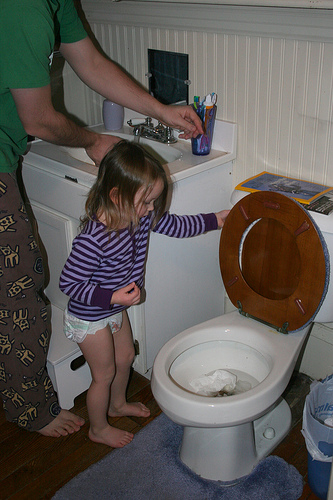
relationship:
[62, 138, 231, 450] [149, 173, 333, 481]
child flushing toilet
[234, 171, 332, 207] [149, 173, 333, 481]
magazine on top of toilet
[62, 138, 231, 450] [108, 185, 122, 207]
child has ear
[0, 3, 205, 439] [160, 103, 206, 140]
man has hand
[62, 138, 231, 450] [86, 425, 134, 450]
child has foot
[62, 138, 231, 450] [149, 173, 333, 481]
child next to toilet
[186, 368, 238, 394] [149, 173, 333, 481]
toilet paper inside of toilet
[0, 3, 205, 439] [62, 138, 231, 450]
man standing next to child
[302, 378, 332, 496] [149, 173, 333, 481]
wastebasket next to toilet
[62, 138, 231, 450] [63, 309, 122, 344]
child wearing diaper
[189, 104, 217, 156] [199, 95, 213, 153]
glass has toothpaste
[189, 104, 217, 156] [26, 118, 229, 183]
glass on top of counter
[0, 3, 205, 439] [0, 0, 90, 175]
man wearing shirt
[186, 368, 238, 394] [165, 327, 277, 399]
toilet paper inside of toilet bowl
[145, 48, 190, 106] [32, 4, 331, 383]
mirror hanging on wall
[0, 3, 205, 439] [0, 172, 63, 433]
man wearing pajama bottoms